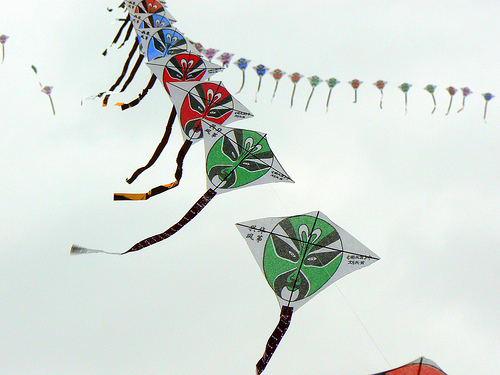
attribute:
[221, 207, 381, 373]
kite — green, colored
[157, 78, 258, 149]
kite — red, colorful, diamond shaped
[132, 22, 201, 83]
kite — blue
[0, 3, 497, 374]
sky — white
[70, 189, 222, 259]
tail — black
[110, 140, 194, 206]
tail — yellow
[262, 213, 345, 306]
design — green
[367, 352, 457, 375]
kite — orange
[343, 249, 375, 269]
word — chinese, black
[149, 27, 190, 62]
mask — blue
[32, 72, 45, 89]
string — connecting